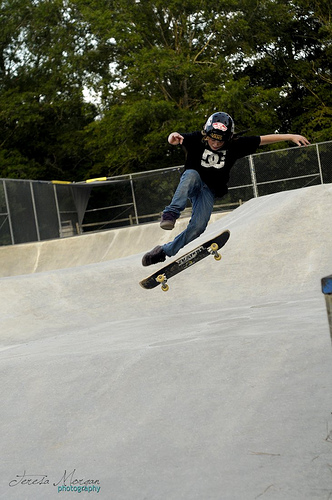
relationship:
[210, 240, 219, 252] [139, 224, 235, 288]
wheel on skateboard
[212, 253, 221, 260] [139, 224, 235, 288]
wheel on skateboard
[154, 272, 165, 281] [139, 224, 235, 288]
wheel on skateboard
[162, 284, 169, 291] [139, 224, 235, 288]
wheel on skateboard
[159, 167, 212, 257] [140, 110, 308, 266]
jeans on boy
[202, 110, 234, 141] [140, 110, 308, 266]
helmet on boy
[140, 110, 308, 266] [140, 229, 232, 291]
boy on skateboard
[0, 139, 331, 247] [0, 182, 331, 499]
fence around park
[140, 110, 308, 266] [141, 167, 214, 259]
boy wearing jeans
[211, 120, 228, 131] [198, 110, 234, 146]
sticker on helmet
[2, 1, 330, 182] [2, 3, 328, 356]
trees in background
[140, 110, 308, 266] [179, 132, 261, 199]
boy wearing a t-shirt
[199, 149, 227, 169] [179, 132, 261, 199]
design on t-shirt